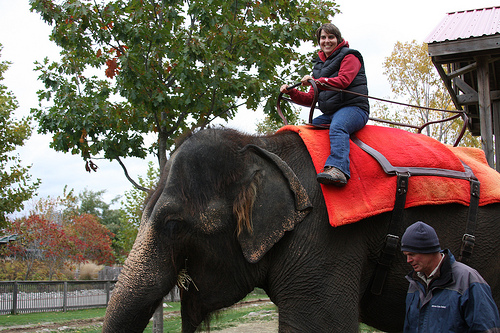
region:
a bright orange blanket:
[273, 106, 498, 236]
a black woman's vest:
[296, 39, 381, 117]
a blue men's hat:
[385, 195, 452, 261]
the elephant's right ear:
[233, 127, 313, 262]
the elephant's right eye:
[163, 203, 195, 239]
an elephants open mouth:
[145, 255, 210, 331]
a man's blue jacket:
[395, 261, 492, 331]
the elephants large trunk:
[78, 235, 177, 329]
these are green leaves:
[34, 68, 120, 135]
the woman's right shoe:
[320, 165, 360, 194]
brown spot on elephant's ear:
[223, 194, 269, 220]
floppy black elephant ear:
[238, 137, 345, 284]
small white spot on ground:
[150, 289, 177, 319]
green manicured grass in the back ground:
[15, 302, 100, 320]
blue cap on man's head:
[390, 218, 453, 247]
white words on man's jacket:
[405, 294, 497, 322]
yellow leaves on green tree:
[68, 27, 156, 69]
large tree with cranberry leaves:
[8, 209, 140, 259]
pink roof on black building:
[401, 2, 483, 71]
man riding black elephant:
[173, 35, 460, 227]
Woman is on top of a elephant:
[97, 12, 498, 332]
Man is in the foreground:
[391, 211, 496, 332]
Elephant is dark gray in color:
[95, 116, 499, 331]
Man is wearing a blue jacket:
[393, 246, 495, 330]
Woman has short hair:
[290, 19, 356, 60]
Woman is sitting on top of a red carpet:
[278, 106, 498, 256]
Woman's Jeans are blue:
[295, 100, 380, 198]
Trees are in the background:
[5, 191, 149, 276]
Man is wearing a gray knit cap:
[388, 215, 460, 283]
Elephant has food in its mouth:
[144, 251, 215, 306]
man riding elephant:
[81, 16, 418, 329]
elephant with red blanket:
[257, 102, 495, 247]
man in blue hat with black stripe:
[391, 214, 467, 331]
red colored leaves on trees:
[10, 196, 151, 291]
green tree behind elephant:
[33, 1, 265, 331]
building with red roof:
[416, 4, 495, 151]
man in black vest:
[274, 24, 380, 159]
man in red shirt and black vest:
[301, 16, 378, 148]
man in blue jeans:
[306, 7, 376, 215]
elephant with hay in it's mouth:
[120, 128, 259, 328]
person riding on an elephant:
[262, 2, 499, 287]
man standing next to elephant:
[314, 195, 495, 327]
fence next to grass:
[3, 274, 103, 319]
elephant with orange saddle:
[122, 112, 484, 299]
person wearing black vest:
[250, 15, 456, 315]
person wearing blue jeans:
[282, 14, 376, 191]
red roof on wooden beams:
[417, 2, 494, 71]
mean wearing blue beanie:
[393, 216, 493, 331]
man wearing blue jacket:
[400, 218, 488, 329]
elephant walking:
[98, 127, 483, 294]